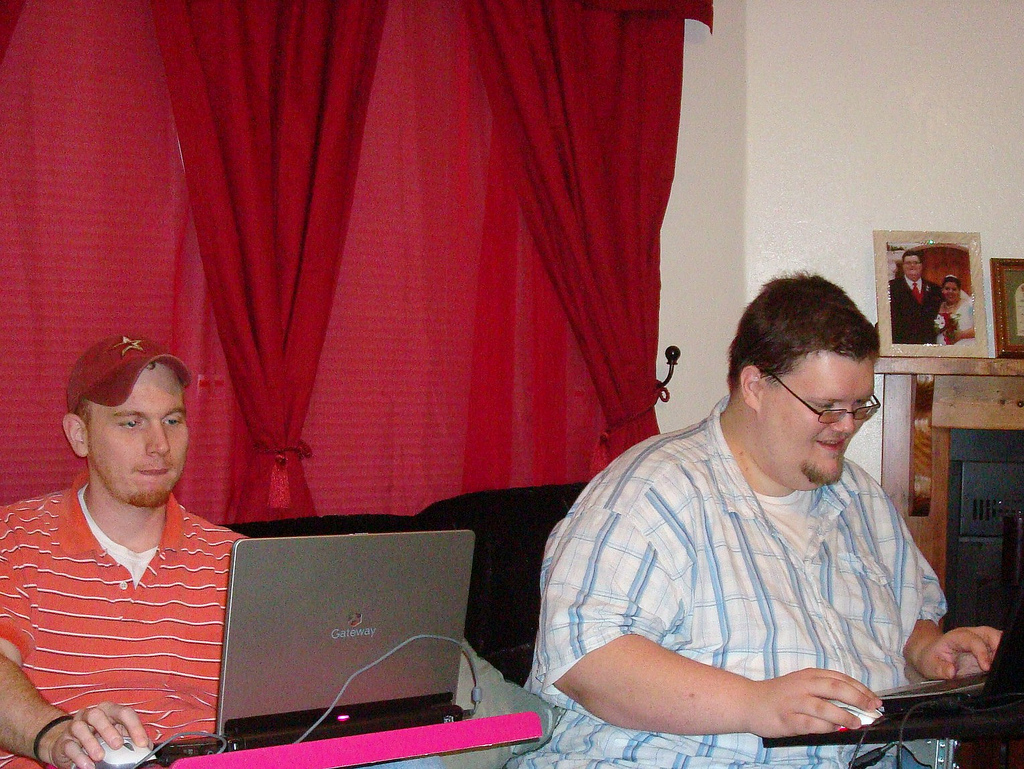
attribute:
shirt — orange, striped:
[19, 476, 331, 757]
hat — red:
[54, 314, 202, 455]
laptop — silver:
[160, 538, 539, 750]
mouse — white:
[82, 711, 158, 763]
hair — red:
[641, 253, 951, 454]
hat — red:
[30, 309, 203, 439]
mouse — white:
[60, 700, 181, 767]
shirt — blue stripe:
[552, 417, 946, 763]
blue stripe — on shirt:
[673, 459, 743, 671]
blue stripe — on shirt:
[660, 439, 753, 653]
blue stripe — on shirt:
[729, 508, 786, 675]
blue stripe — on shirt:
[567, 513, 628, 634]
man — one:
[8, 336, 237, 725]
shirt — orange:
[11, 500, 238, 712]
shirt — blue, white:
[553, 474, 949, 762]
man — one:
[631, 273, 953, 736]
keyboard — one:
[764, 661, 991, 765]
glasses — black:
[776, 392, 904, 445]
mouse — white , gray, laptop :
[70, 711, 166, 766]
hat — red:
[49, 331, 164, 409]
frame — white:
[871, 223, 992, 370]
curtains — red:
[27, 39, 684, 470]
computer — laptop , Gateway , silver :
[200, 519, 477, 749]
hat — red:
[48, 318, 183, 407]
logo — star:
[94, 335, 149, 370]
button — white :
[796, 536, 829, 586]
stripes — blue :
[669, 448, 819, 699]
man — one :
[602, 245, 948, 710]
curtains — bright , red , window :
[38, 5, 657, 459]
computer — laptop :
[193, 515, 500, 742]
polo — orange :
[20, 499, 237, 722]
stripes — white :
[27, 586, 200, 693]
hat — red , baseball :
[66, 331, 194, 401]